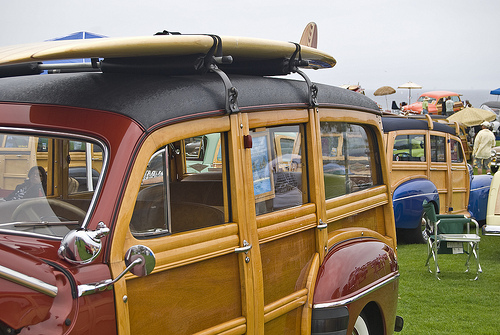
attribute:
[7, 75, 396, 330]
vehicle — old, red, yellow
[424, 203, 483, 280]
chair — green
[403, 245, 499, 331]
grass — green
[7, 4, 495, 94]
sky — overcast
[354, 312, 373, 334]
wheel — red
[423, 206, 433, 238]
wheel — blue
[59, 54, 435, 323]
car — woody